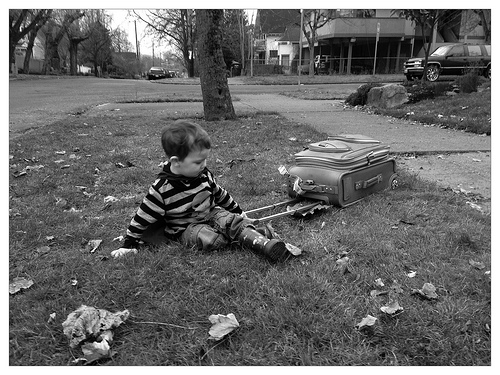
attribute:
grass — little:
[71, 256, 257, 331]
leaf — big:
[45, 296, 178, 350]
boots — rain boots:
[238, 220, 295, 263]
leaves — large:
[57, 302, 139, 359]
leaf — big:
[58, 302, 136, 359]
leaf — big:
[206, 308, 245, 340]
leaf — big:
[193, 289, 268, 366]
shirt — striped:
[122, 161, 242, 246]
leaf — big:
[408, 284, 445, 301]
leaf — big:
[63, 305, 131, 340]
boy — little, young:
[113, 118, 286, 260]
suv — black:
[401, 40, 492, 82]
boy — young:
[109, 118, 297, 265]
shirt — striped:
[118, 165, 242, 250]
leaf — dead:
[202, 312, 238, 359]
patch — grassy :
[69, 114, 354, 374]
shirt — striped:
[113, 144, 230, 214]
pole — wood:
[116, 13, 178, 81]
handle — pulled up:
[237, 191, 326, 221]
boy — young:
[88, 111, 318, 287]